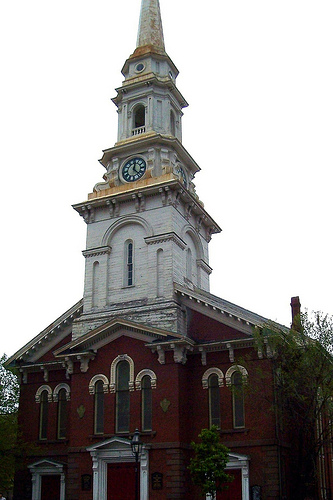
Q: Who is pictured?
A: No one is pictured.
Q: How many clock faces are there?
A: Two.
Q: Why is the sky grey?
A: It is overcast.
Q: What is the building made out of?
A: Brick.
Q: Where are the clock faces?
A: On the clocktower.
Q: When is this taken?
A: Daytime.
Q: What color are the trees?
A: Green.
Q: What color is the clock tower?
A: White and gold.